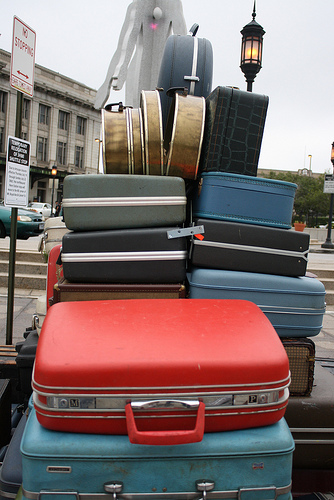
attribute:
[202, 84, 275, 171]
luggage — round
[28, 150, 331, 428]
suitcases — red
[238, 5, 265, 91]
lamp — illuminated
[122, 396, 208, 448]
handle — red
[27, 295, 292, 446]
suitcase — red, blue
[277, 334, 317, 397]
checkered suitcase — tan and checkered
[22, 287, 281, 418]
suit case — red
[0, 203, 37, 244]
car — green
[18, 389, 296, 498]
suitcase — blue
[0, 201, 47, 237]
car — greenish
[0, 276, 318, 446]
suitcase — red 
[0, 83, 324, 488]
suitcases — large 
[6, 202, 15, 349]
pole — black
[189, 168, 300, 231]
blue suitcase — large and light blue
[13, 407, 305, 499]
suitcase — blue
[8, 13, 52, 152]
sign — white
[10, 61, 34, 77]
arrow — red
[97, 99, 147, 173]
luggage — round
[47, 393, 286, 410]
accents — silver 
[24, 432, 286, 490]
scruff marks — brown